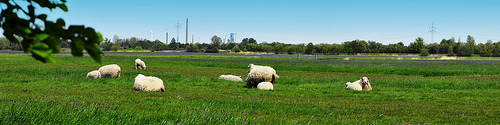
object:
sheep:
[345, 81, 363, 91]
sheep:
[84, 64, 121, 79]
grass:
[137, 95, 184, 105]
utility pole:
[186, 17, 189, 46]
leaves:
[0, 0, 104, 64]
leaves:
[344, 41, 353, 52]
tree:
[344, 39, 369, 53]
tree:
[448, 44, 455, 56]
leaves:
[448, 45, 455, 56]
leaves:
[167, 37, 176, 47]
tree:
[167, 38, 179, 50]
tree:
[150, 39, 170, 50]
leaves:
[150, 39, 168, 52]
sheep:
[244, 63, 278, 88]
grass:
[0, 52, 500, 122]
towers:
[185, 17, 188, 49]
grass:
[380, 74, 500, 89]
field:
[0, 42, 500, 122]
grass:
[0, 97, 284, 125]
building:
[230, 33, 237, 43]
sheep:
[352, 76, 372, 91]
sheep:
[257, 82, 273, 90]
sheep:
[133, 58, 146, 70]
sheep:
[98, 64, 120, 78]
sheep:
[132, 73, 165, 92]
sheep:
[86, 70, 101, 79]